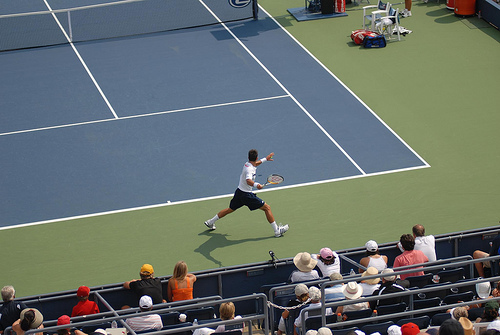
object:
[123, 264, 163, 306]
person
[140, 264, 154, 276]
hat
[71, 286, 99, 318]
person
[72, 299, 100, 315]
shirt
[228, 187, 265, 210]
shorts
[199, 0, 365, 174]
lines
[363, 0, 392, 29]
judge's chair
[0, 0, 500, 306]
court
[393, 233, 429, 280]
spectator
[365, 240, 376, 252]
cap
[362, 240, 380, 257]
head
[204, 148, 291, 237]
guy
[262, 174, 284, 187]
racket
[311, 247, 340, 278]
woman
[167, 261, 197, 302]
girl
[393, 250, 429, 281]
shirt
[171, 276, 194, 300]
tank top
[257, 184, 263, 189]
hand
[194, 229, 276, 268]
shadow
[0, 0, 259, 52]
net